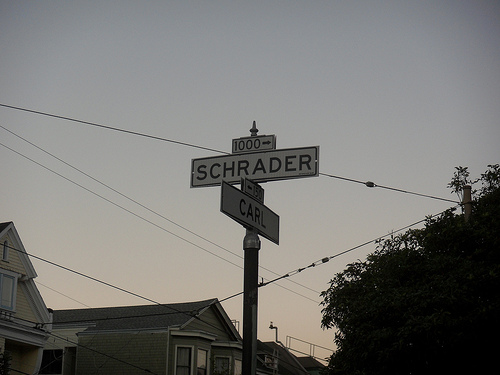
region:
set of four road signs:
[190, 119, 310, 301]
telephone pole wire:
[204, 260, 384, 300]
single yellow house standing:
[0, 210, 57, 372]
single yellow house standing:
[54, 289, 271, 364]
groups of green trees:
[340, 205, 482, 371]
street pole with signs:
[198, 113, 323, 344]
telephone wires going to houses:
[7, 80, 421, 365]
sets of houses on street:
[5, 222, 320, 374]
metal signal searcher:
[270, 320, 347, 362]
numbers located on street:
[170, 133, 337, 183]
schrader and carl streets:
[175, 79, 407, 243]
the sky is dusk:
[156, 112, 459, 323]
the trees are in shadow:
[338, 181, 495, 328]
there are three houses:
[6, 205, 312, 373]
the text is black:
[163, 121, 358, 264]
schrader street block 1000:
[176, 112, 371, 281]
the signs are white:
[179, 110, 369, 270]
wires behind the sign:
[150, 105, 411, 297]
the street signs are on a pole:
[174, 106, 385, 306]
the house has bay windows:
[139, 277, 291, 359]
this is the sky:
[146, 28, 388, 114]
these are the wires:
[33, 149, 83, 191]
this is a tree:
[378, 247, 488, 357]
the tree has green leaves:
[425, 258, 460, 295]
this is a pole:
[461, 185, 468, 212]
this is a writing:
[194, 158, 308, 173]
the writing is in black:
[206, 158, 280, 175]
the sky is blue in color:
[276, 30, 360, 85]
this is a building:
[95, 302, 200, 374]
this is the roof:
[99, 306, 179, 326]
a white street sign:
[163, 105, 333, 256]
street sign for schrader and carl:
[168, 100, 350, 273]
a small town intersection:
[0, 72, 496, 367]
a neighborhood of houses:
[3, 192, 353, 373]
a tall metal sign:
[143, 88, 341, 371]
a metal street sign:
[141, 93, 338, 373]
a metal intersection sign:
[6, 97, 418, 370]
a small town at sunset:
[6, 74, 493, 374]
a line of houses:
[7, 62, 457, 372]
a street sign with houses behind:
[8, 80, 483, 372]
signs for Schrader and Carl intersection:
[166, 91, 351, 371]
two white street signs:
[169, 112, 334, 255]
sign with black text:
[218, 175, 308, 250]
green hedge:
[324, 180, 491, 370]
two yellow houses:
[1, 223, 239, 373]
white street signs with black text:
[186, 79, 332, 372]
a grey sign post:
[234, 241, 266, 373]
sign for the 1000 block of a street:
[229, 133, 279, 153]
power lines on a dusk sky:
[6, 78, 169, 210]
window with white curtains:
[171, 340, 194, 372]